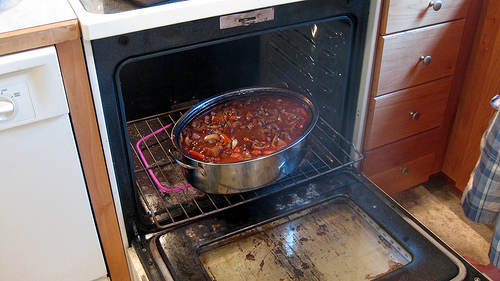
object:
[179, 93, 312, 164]
stew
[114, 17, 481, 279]
oven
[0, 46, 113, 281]
dishwasher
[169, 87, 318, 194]
pot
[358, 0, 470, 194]
cabinet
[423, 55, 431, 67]
knob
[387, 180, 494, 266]
floor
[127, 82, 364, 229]
grate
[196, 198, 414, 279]
window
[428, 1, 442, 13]
knob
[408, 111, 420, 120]
knob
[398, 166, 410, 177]
knob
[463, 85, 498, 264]
shirt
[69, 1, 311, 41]
top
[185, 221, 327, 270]
food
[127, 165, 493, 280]
oven door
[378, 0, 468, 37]
drawer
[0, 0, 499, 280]
kitchen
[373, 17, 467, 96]
drawer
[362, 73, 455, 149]
drawer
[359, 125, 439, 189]
drawer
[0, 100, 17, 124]
knob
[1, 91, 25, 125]
wash cycles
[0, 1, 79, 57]
counter top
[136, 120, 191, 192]
heated wire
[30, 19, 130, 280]
frame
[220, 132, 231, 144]
carrot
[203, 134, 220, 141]
mushroom